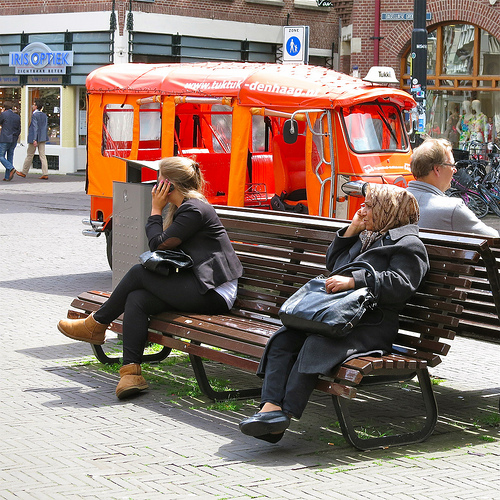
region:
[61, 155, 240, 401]
A lady sits on the bench.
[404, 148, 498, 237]
A man sits on a bench.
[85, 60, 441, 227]
A shuttle bus sits on the curb.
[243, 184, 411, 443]
A lady sits on the bench.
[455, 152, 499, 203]
Bikes sit on the curb.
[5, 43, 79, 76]
The store sign.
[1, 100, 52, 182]
Two men walk down the street.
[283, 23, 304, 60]
A street sign.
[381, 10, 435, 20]
A street sign.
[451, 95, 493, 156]
Mannequins in the window.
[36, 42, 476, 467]
Some people are sitting on benches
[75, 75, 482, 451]
Some people are waiting for a bus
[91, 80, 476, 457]
Some people are talking to someone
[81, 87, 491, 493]
The people are in a city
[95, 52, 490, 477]
Some people are doing some shopping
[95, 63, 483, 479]
Some people are out in the daytime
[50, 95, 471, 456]
Some people are dressed very nicely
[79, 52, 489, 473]
The people are enjoying their day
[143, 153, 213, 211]
head of a person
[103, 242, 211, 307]
thigh of a person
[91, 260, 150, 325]
leg of a person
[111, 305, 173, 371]
leg of a person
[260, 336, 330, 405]
leg of a person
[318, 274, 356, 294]
hand of a person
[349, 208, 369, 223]
hand of a person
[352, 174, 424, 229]
head of a person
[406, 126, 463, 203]
head of a person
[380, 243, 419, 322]
arm of a person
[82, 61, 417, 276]
an orange bus parked behind benches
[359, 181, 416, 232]
woman with scarf on head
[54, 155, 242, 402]
young woman sits cross legged on bench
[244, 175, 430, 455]
old woman sits with ankles crossed on bench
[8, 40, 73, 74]
sign reads Iris Optek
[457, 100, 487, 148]
mannequins posing in store window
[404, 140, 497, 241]
man wearing glasses sits on bench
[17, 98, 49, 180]
man in blazer walks down the street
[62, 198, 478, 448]
a brown wooden public bench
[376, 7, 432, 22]
blue sign indicates name of street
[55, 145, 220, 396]
woman sitting on bench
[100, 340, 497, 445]
grass beneath the bench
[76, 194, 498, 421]
bench with people sitting on it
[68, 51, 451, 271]
small bus to carry passengers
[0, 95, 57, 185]
people walking down the street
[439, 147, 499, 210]
bikes in front of store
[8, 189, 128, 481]
road made from bricks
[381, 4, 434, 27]
plaque on the building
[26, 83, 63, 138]
window to the store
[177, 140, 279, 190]
seating inside the bus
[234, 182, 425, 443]
woman is sitting on the bench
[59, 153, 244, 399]
woman is sitting on the bench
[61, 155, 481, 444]
two women sitting on a bench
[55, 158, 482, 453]
two women talking on their phones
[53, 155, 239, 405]
a woman wearing brown boots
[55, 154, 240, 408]
a woman with light color hair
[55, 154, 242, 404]
a woman wearing black tight pants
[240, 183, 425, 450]
a woman wearing a brown scarf on her head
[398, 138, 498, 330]
a man sitting on a bench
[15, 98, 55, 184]
a man wearing khaki pants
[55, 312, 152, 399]
a pair of brown boots